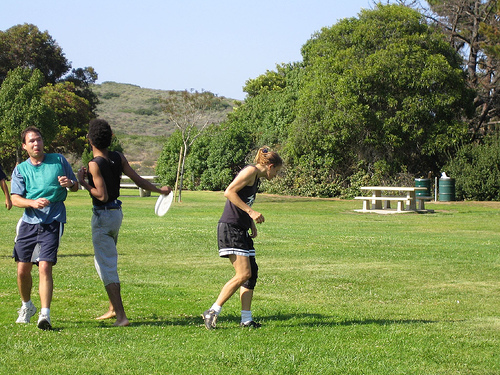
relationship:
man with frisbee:
[76, 118, 171, 327] [150, 184, 178, 219]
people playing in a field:
[26, 119, 326, 329] [194, 205, 470, 304]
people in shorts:
[0, 118, 284, 331] [214, 217, 259, 259]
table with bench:
[359, 178, 426, 201] [355, 193, 414, 214]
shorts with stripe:
[13, 217, 62, 272] [15, 218, 22, 240]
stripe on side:
[15, 218, 22, 240] [9, 220, 25, 260]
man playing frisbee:
[76, 118, 171, 327] [154, 182, 182, 215]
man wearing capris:
[74, 113, 172, 331] [88, 198, 128, 289]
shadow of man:
[52, 306, 442, 338] [76, 118, 171, 327]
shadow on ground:
[52, 306, 442, 338] [32, 293, 486, 358]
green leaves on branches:
[0, 0, 499, 203] [345, 30, 415, 59]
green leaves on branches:
[0, 0, 499, 203] [307, 88, 354, 114]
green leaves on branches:
[478, 22, 498, 62] [460, 3, 499, 136]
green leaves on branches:
[0, 0, 499, 203] [349, 133, 388, 158]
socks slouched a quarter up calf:
[229, 306, 262, 332] [212, 296, 227, 306]